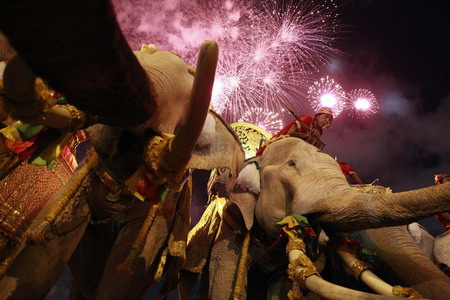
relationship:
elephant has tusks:
[206, 134, 444, 298] [287, 239, 409, 297]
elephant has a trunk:
[206, 134, 444, 298] [322, 181, 450, 231]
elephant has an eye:
[206, 134, 444, 298] [285, 160, 298, 168]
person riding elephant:
[281, 106, 338, 152] [206, 134, 444, 298]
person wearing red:
[281, 106, 338, 152] [296, 114, 310, 126]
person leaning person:
[281, 106, 338, 152] [254, 106, 333, 156]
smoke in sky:
[135, 4, 210, 45] [331, 4, 448, 80]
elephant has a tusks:
[206, 134, 444, 298] [286, 239, 427, 299]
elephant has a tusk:
[6, 1, 238, 299] [144, 34, 231, 193]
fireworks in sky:
[209, 0, 380, 137] [331, 4, 448, 80]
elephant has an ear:
[206, 134, 444, 298] [226, 152, 263, 229]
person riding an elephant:
[281, 106, 338, 152] [206, 134, 444, 298]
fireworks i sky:
[215, 0, 383, 107] [331, 4, 448, 80]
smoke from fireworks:
[135, 4, 210, 45] [215, 0, 383, 107]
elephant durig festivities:
[206, 134, 444, 298] [1, 4, 448, 294]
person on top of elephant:
[281, 106, 338, 152] [206, 134, 444, 298]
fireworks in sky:
[215, 0, 383, 107] [331, 4, 448, 80]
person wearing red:
[254, 106, 333, 156] [296, 114, 310, 126]